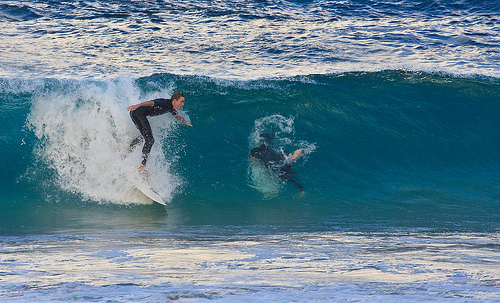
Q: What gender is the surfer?
A: Male.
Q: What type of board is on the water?
A: Surf board.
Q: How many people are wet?
A: 2.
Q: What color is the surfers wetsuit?
A: Black.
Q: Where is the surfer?
A: On the surfboard.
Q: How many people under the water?
A: 1.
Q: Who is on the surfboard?
A: The man.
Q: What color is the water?
A: Blue.